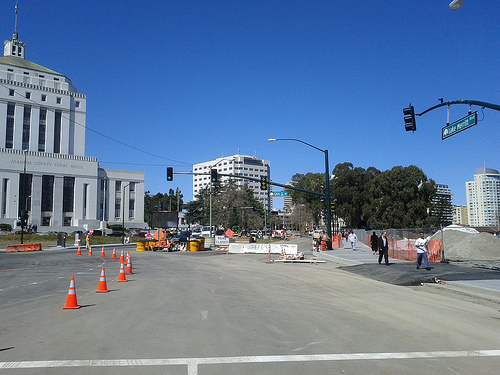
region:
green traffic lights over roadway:
[134, 141, 298, 190]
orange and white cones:
[34, 256, 160, 327]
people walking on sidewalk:
[346, 226, 480, 273]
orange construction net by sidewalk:
[367, 228, 461, 274]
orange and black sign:
[133, 215, 177, 258]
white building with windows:
[187, 139, 310, 223]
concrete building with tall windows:
[12, 143, 158, 241]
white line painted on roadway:
[156, 345, 466, 369]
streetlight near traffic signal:
[251, 121, 360, 275]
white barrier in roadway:
[221, 233, 330, 270]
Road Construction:
[111, 208, 498, 338]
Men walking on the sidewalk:
[338, 223, 467, 326]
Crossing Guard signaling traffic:
[8, 218, 143, 340]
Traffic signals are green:
[129, 136, 375, 291]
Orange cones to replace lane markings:
[0, 234, 135, 343]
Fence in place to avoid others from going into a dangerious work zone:
[329, 126, 496, 353]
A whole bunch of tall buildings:
[5, 3, 499, 265]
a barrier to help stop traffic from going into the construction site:
[210, 208, 319, 289]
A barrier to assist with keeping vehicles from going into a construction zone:
[2, 216, 52, 269]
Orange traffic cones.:
[80, 237, 140, 313]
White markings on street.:
[40, 333, 484, 371]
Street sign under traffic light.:
[432, 107, 493, 138]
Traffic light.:
[398, 93, 421, 135]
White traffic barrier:
[230, 237, 306, 255]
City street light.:
[257, 134, 326, 151]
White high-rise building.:
[186, 147, 281, 209]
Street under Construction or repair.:
[143, 225, 323, 270]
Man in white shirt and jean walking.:
[412, 230, 427, 270]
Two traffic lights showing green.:
[150, 160, 234, 185]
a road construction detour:
[15, 221, 445, 358]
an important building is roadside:
[3, 5, 144, 243]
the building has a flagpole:
[3, 2, 83, 96]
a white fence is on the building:
[0, 55, 79, 94]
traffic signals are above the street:
[158, 97, 434, 202]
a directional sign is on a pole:
[437, 91, 482, 143]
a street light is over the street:
[263, 128, 343, 255]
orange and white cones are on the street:
[62, 245, 134, 311]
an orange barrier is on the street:
[1, 241, 44, 253]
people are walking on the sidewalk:
[336, 222, 441, 273]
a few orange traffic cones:
[53, 232, 140, 324]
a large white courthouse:
[1, 17, 177, 266]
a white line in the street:
[58, 337, 495, 372]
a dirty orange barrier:
[1, 240, 51, 262]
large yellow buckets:
[183, 236, 218, 251]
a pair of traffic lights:
[153, 160, 240, 190]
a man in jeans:
[409, 228, 431, 276]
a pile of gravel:
[441, 221, 498, 269]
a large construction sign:
[145, 202, 190, 237]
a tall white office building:
[176, 147, 300, 245]